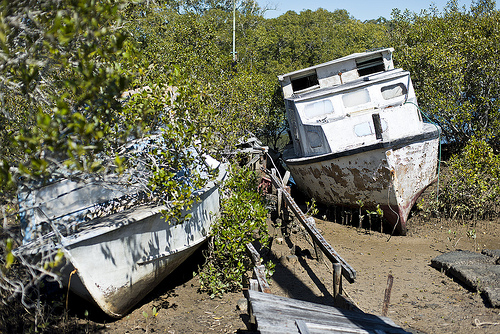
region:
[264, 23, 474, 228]
a boat on the ground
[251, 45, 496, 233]
a boat on the ground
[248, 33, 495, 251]
a boat on the ground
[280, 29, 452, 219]
a boat on the ground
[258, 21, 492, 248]
a boat on the ground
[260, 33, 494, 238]
a boat on the ground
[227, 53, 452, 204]
a boat on the ground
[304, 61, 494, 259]
a boat on the ground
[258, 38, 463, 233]
boat shipwrecked on sand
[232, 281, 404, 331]
broken dock on the sand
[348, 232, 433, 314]
dirt ground under boats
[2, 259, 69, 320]
bare branch of a tree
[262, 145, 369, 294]
fence along side a dock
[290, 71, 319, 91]
window of a boat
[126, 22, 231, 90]
green leaves of trees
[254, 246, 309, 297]
shadow on the ground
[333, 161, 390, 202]
peeling paint on a boat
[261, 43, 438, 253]
white boat stuck in mud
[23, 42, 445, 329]
two light colored boat on land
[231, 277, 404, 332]
broken weathered wooden dock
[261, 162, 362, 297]
section of old rotted wooden railing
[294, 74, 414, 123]
three rectangular shaped boat windows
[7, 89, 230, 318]
one boat partially covered by tree branches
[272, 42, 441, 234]
one sunlit boat next to trees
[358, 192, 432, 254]
bottom of boat in dirt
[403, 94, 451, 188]
one green hose trailing down boat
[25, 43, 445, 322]
two boats with tree branches in between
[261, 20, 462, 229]
boat on the ground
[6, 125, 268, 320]
boat on the ground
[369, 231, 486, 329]
dirt on the ground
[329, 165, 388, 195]
weathered side of the boat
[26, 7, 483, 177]
trees in the back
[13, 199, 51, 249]
fabric on the boat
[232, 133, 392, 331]
a recked wood bridge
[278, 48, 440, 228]
an old recked boat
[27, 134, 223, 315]
an old white boat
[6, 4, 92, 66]
part of the leafy trees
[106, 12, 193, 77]
part of the leafy trees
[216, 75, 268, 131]
part of the leafy trees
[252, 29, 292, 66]
part of the leafy trees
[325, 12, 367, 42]
part of the leafy trees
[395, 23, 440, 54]
part of the leafy trees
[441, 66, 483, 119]
part of the leafy trees